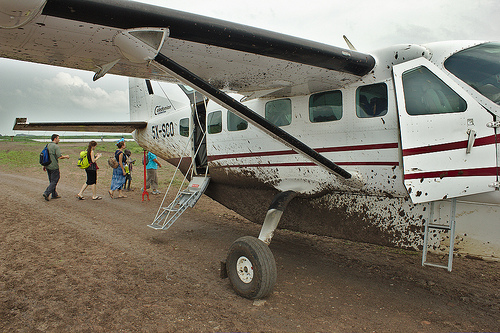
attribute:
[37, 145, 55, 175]
backpack — blue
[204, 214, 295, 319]
tire — large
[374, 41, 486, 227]
door — cockpit, red, back, plane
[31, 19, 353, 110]
wing — black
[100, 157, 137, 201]
dress — blue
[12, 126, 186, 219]
people — walking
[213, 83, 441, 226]
plane — small, white, air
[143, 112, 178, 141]
letter — black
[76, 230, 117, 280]
ground — brown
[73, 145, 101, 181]
backpack — green, yellow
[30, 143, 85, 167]
shirt — blue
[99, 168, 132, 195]
skirt — woman, blue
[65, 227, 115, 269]
dirt — runaway